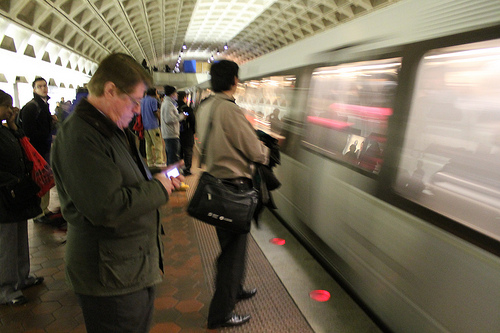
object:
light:
[307, 288, 334, 303]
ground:
[0, 160, 289, 329]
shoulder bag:
[186, 100, 257, 235]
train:
[189, 1, 499, 333]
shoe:
[205, 312, 254, 329]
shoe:
[236, 287, 259, 301]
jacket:
[48, 101, 168, 296]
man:
[140, 86, 167, 169]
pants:
[142, 127, 168, 166]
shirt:
[140, 96, 159, 128]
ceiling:
[1, 0, 394, 50]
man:
[51, 53, 185, 333]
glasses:
[116, 86, 144, 107]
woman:
[0, 89, 45, 305]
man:
[194, 60, 268, 328]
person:
[18, 79, 57, 226]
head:
[145, 85, 157, 98]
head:
[88, 52, 153, 129]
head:
[0, 90, 14, 122]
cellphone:
[163, 165, 183, 181]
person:
[160, 84, 188, 166]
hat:
[163, 84, 176, 96]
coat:
[254, 126, 283, 232]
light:
[268, 234, 287, 246]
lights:
[221, 41, 231, 51]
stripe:
[249, 206, 381, 333]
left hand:
[164, 159, 186, 189]